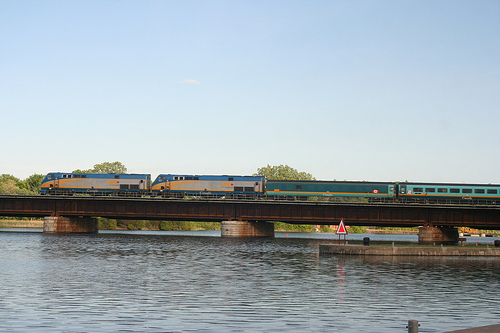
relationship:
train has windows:
[37, 173, 496, 205] [416, 183, 500, 199]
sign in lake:
[330, 218, 353, 232] [0, 228, 500, 333]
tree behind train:
[3, 163, 135, 202] [37, 173, 496, 205]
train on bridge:
[37, 173, 496, 205] [39, 208, 500, 247]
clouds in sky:
[90, 68, 332, 124] [46, 27, 452, 144]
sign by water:
[330, 218, 353, 232] [49, 252, 441, 328]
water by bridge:
[49, 252, 441, 328] [39, 208, 500, 247]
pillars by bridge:
[33, 212, 113, 241] [39, 208, 500, 247]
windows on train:
[416, 183, 500, 199] [37, 173, 496, 205]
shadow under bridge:
[207, 244, 354, 284] [39, 208, 500, 247]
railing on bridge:
[122, 191, 282, 203] [39, 208, 500, 247]